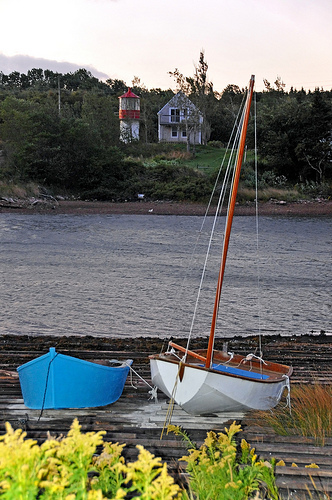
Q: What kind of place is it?
A: It is a forest.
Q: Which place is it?
A: It is a forest.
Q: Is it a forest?
A: Yes, it is a forest.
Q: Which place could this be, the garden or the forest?
A: It is the forest.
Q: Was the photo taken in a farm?
A: No, the picture was taken in a forest.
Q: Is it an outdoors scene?
A: Yes, it is outdoors.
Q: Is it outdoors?
A: Yes, it is outdoors.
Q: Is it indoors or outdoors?
A: It is outdoors.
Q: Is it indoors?
A: No, it is outdoors.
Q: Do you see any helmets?
A: No, there are no helmets.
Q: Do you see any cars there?
A: No, there are no cars.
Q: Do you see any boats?
A: Yes, there is a boat.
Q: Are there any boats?
A: Yes, there is a boat.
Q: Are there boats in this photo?
A: Yes, there is a boat.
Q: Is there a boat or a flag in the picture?
A: Yes, there is a boat.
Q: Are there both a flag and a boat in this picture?
A: No, there is a boat but no flags.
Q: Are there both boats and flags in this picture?
A: No, there is a boat but no flags.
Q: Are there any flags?
A: No, there are no flags.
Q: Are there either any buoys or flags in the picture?
A: No, there are no flags or buoys.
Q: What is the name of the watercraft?
A: The watercraft is a boat.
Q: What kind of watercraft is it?
A: The watercraft is a boat.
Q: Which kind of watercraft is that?
A: That is a boat.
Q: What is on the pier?
A: The boat is on the pier.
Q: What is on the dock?
A: The boat is on the pier.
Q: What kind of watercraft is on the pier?
A: The watercraft is a boat.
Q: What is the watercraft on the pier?
A: The watercraft is a boat.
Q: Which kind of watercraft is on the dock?
A: The watercraft is a boat.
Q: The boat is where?
A: The boat is on the dock.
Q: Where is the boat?
A: The boat is on the dock.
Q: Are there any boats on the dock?
A: Yes, there is a boat on the dock.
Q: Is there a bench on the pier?
A: No, there is a boat on the pier.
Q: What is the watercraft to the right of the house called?
A: The watercraft is a boat.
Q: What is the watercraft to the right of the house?
A: The watercraft is a boat.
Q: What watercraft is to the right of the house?
A: The watercraft is a boat.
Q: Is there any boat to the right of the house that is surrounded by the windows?
A: Yes, there is a boat to the right of the house.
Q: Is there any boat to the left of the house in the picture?
A: No, the boat is to the right of the house.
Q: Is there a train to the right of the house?
A: No, there is a boat to the right of the house.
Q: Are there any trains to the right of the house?
A: No, there is a boat to the right of the house.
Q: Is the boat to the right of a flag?
A: No, the boat is to the right of a house.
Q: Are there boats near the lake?
A: Yes, there is a boat near the lake.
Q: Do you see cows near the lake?
A: No, there is a boat near the lake.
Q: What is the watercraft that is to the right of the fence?
A: The watercraft is a boat.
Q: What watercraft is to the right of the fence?
A: The watercraft is a boat.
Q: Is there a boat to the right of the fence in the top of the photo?
A: Yes, there is a boat to the right of the fence.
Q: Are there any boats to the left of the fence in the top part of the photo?
A: No, the boat is to the right of the fence.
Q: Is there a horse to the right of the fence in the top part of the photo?
A: No, there is a boat to the right of the fence.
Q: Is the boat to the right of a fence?
A: Yes, the boat is to the right of a fence.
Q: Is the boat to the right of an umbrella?
A: No, the boat is to the right of a fence.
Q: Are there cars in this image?
A: No, there are no cars.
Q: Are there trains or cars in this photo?
A: No, there are no cars or trains.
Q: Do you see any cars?
A: No, there are no cars.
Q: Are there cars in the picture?
A: No, there are no cars.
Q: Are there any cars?
A: No, there are no cars.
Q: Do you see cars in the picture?
A: No, there are no cars.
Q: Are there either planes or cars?
A: No, there are no cars or planes.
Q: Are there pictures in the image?
A: No, there are no pictures.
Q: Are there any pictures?
A: No, there are no pictures.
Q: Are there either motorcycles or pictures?
A: No, there are no pictures or motorcycles.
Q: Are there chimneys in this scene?
A: No, there are no chimneys.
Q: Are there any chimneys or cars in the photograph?
A: No, there are no chimneys or cars.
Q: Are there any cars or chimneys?
A: No, there are no chimneys or cars.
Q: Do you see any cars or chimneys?
A: No, there are no chimneys or cars.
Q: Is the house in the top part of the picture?
A: Yes, the house is in the top of the image.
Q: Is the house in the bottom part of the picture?
A: No, the house is in the top of the image.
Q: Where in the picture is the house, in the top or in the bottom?
A: The house is in the top of the image.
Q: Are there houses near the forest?
A: Yes, there is a house near the forest.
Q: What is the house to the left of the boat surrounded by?
A: The house is surrounded by the windows.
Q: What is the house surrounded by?
A: The house is surrounded by the windows.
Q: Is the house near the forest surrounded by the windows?
A: Yes, the house is surrounded by the windows.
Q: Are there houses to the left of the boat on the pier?
A: Yes, there is a house to the left of the boat.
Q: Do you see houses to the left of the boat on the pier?
A: Yes, there is a house to the left of the boat.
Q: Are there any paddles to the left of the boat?
A: No, there is a house to the left of the boat.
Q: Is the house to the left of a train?
A: No, the house is to the left of the boat.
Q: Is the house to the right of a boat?
A: No, the house is to the left of a boat.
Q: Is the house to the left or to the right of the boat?
A: The house is to the left of the boat.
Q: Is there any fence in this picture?
A: Yes, there is a fence.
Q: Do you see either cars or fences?
A: Yes, there is a fence.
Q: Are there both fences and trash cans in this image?
A: No, there is a fence but no trash cans.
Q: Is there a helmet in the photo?
A: No, there are no helmets.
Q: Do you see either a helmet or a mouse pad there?
A: No, there are no helmets or mouse pads.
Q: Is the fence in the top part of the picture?
A: Yes, the fence is in the top of the image.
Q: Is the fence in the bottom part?
A: No, the fence is in the top of the image.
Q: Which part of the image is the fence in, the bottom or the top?
A: The fence is in the top of the image.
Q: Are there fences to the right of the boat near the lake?
A: No, the fence is to the left of the boat.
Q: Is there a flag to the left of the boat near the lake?
A: No, there is a fence to the left of the boat.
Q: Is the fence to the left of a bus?
A: No, the fence is to the left of the boat.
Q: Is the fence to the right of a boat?
A: No, the fence is to the left of a boat.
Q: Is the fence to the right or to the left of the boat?
A: The fence is to the left of the boat.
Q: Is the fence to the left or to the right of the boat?
A: The fence is to the left of the boat.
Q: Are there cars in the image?
A: No, there are no cars.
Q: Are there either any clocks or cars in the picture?
A: No, there are no cars or clocks.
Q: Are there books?
A: No, there are no books.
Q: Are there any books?
A: No, there are no books.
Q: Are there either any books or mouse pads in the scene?
A: No, there are no books or mouse pads.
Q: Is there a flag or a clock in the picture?
A: No, there are no flags or clocks.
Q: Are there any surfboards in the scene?
A: No, there are no surfboards.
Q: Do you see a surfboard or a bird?
A: No, there are no surfboards or birds.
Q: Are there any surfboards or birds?
A: No, there are no surfboards or birds.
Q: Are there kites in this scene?
A: No, there are no kites.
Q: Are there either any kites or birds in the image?
A: No, there are no kites or birds.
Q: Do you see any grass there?
A: Yes, there is grass.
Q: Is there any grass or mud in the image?
A: Yes, there is grass.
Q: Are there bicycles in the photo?
A: No, there are no bicycles.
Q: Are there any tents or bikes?
A: No, there are no bikes or tents.